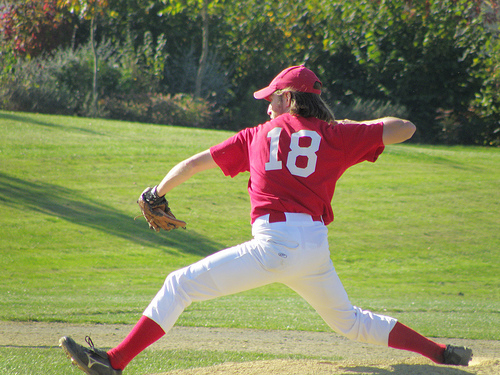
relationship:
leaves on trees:
[211, 0, 396, 56] [1, 0, 497, 143]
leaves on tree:
[72, 0, 219, 32] [80, 22, 211, 103]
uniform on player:
[143, 69, 442, 372] [121, 36, 494, 372]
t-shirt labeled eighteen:
[210, 108, 385, 228] [250, 117, 399, 233]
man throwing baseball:
[157, 74, 434, 374] [144, 25, 447, 369]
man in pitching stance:
[59, 63, 478, 374] [133, 60, 493, 355]